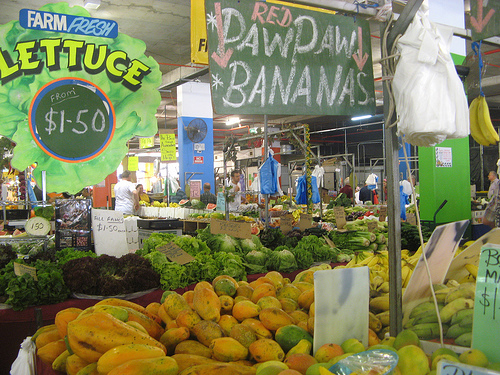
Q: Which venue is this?
A: This is a market.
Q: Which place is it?
A: It is a market.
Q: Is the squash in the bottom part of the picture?
A: Yes, the squash is in the bottom of the image.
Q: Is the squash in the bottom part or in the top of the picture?
A: The squash is in the bottom of the image.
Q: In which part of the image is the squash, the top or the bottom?
A: The squash is in the bottom of the image.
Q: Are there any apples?
A: No, there are no apples.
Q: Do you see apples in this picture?
A: No, there are no apples.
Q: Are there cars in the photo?
A: No, there are no cars.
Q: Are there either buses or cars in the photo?
A: No, there are no cars or buses.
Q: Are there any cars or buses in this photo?
A: No, there are no cars or buses.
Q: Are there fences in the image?
A: No, there are no fences.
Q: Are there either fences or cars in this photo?
A: No, there are no fences or cars.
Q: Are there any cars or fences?
A: No, there are no fences or cars.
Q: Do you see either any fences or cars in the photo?
A: No, there are no fences or cars.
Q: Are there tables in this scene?
A: Yes, there is a table.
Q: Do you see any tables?
A: Yes, there is a table.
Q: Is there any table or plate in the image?
A: Yes, there is a table.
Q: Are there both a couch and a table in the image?
A: No, there is a table but no couches.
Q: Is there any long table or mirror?
A: Yes, there is a long table.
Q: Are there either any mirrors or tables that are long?
A: Yes, the table is long.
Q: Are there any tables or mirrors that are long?
A: Yes, the table is long.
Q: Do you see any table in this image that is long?
A: Yes, there is a long table.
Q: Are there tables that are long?
A: Yes, there is a table that is long.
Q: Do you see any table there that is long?
A: Yes, there is a table that is long.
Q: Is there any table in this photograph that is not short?
A: Yes, there is a long table.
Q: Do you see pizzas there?
A: No, there are no pizzas.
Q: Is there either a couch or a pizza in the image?
A: No, there are no pizzas or couches.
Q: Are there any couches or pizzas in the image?
A: No, there are no pizzas or couches.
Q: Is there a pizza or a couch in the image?
A: No, there are no pizzas or couches.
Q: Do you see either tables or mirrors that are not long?
A: No, there is a table but it is long.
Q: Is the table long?
A: Yes, the table is long.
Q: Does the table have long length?
A: Yes, the table is long.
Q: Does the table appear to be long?
A: Yes, the table is long.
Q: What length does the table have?
A: The table has long length.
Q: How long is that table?
A: The table is long.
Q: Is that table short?
A: No, the table is long.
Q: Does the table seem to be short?
A: No, the table is long.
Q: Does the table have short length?
A: No, the table is long.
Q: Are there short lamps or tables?
A: No, there is a table but it is long.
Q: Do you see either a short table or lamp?
A: No, there is a table but it is long.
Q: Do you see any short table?
A: No, there is a table but it is long.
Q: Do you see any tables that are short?
A: No, there is a table but it is long.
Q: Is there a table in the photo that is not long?
A: No, there is a table but it is long.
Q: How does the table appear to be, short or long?
A: The table is long.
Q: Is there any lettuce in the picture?
A: Yes, there is lettuce.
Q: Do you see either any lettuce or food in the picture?
A: Yes, there is lettuce.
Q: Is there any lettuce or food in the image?
A: Yes, there is lettuce.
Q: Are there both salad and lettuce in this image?
A: No, there is lettuce but no salad.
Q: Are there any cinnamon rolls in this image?
A: No, there are no cinnamon rolls.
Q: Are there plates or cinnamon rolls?
A: No, there are no cinnamon rolls or plates.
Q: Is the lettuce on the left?
A: Yes, the lettuce is on the left of the image.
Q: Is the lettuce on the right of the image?
A: No, the lettuce is on the left of the image.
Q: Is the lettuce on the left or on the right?
A: The lettuce is on the left of the image.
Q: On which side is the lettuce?
A: The lettuce is on the left of the image.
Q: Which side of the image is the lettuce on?
A: The lettuce is on the left of the image.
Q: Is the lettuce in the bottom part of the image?
A: Yes, the lettuce is in the bottom of the image.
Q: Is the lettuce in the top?
A: No, the lettuce is in the bottom of the image.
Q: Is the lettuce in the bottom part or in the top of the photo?
A: The lettuce is in the bottom of the image.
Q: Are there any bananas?
A: Yes, there is a banana.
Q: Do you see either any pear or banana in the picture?
A: Yes, there is a banana.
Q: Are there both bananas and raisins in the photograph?
A: No, there is a banana but no raisins.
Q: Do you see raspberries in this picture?
A: No, there are no raspberries.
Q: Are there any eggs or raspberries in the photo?
A: No, there are no raspberries or eggs.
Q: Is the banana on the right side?
A: Yes, the banana is on the right of the image.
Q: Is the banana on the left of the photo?
A: No, the banana is on the right of the image.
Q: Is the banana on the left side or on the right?
A: The banana is on the right of the image.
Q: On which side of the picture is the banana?
A: The banana is on the right of the image.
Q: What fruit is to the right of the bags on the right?
A: The fruit is a banana.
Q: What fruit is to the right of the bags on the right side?
A: The fruit is a banana.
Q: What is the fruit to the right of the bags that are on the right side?
A: The fruit is a banana.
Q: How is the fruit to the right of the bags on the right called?
A: The fruit is a banana.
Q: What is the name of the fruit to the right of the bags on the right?
A: The fruit is a banana.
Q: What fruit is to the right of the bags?
A: The fruit is a banana.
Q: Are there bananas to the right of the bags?
A: Yes, there is a banana to the right of the bags.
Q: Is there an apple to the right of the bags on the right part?
A: No, there is a banana to the right of the bags.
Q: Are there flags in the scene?
A: No, there are no flags.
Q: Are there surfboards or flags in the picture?
A: No, there are no flags or surfboards.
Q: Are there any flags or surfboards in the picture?
A: No, there are no flags or surfboards.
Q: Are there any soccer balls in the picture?
A: No, there are no soccer balls.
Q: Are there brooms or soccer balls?
A: No, there are no soccer balls or brooms.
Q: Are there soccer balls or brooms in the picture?
A: No, there are no soccer balls or brooms.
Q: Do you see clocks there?
A: No, there are no clocks.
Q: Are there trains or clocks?
A: No, there are no clocks or trains.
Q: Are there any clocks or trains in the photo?
A: No, there are no clocks or trains.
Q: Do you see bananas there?
A: Yes, there is a banana.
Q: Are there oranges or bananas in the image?
A: Yes, there is a banana.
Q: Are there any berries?
A: No, there are no berries.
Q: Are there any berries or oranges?
A: No, there are no berries or oranges.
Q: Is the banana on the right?
A: Yes, the banana is on the right of the image.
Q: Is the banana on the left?
A: No, the banana is on the right of the image.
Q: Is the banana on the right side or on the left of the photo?
A: The banana is on the right of the image.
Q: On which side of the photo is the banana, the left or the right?
A: The banana is on the right of the image.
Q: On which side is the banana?
A: The banana is on the right of the image.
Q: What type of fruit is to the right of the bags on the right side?
A: The fruit is a banana.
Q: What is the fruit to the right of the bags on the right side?
A: The fruit is a banana.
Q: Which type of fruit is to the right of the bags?
A: The fruit is a banana.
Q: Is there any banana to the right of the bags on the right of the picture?
A: Yes, there is a banana to the right of the bags.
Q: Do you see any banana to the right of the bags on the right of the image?
A: Yes, there is a banana to the right of the bags.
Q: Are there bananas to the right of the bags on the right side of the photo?
A: Yes, there is a banana to the right of the bags.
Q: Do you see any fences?
A: No, there are no fences.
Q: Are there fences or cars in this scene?
A: No, there are no fences or cars.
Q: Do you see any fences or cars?
A: No, there are no fences or cars.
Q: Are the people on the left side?
A: Yes, the people are on the left of the image.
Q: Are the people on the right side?
A: No, the people are on the left of the image.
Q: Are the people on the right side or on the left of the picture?
A: The people are on the left of the image.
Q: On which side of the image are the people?
A: The people are on the left of the image.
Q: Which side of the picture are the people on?
A: The people are on the left of the image.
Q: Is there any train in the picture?
A: No, there are no trains.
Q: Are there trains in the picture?
A: No, there are no trains.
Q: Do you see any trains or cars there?
A: No, there are no trains or cars.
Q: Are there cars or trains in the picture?
A: No, there are no trains or cars.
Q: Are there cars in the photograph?
A: No, there are no cars.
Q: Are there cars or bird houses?
A: No, there are no cars or bird houses.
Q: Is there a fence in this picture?
A: No, there are no fences.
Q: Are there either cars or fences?
A: No, there are no fences or cars.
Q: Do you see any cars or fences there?
A: No, there are no fences or cars.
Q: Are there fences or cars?
A: No, there are no fences or cars.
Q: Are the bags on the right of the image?
A: Yes, the bags are on the right of the image.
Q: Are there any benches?
A: No, there are no benches.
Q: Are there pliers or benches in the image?
A: No, there are no benches or pliers.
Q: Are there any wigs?
A: No, there are no wigs.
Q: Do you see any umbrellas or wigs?
A: No, there are no wigs or umbrellas.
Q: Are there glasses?
A: No, there are no glasses.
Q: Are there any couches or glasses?
A: No, there are no glasses or couches.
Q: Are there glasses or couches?
A: No, there are no glasses or couches.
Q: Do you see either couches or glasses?
A: No, there are no glasses or couches.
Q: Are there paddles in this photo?
A: No, there are no paddles.